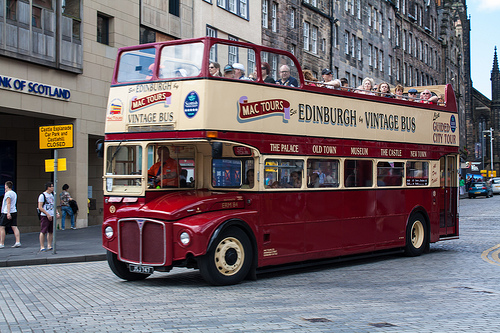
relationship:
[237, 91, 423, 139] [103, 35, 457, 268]
words on bus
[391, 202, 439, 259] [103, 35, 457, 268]
tires on bus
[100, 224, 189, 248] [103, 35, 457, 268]
lights on bus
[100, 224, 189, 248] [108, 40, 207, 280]
lights in front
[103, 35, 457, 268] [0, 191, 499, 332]
bus on street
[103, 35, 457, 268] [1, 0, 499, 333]
bus in city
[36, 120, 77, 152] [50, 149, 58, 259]
sign on pole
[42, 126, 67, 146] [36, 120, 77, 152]
letters on sign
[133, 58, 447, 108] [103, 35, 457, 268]
people on bus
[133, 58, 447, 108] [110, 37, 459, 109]
people on top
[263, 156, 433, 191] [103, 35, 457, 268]
windows on bus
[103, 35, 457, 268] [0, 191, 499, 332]
bus on road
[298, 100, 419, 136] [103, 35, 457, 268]
lettering on bus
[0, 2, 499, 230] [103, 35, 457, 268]
buildings behind bus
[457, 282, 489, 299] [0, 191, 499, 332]
drain on street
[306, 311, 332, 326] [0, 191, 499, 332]
spot on street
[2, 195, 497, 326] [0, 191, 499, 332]
tiles on road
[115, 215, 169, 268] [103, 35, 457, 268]
grate on bus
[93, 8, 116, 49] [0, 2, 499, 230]
window in building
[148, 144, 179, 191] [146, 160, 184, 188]
bus driver wearing shirt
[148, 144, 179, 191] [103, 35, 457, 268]
bus driver on bus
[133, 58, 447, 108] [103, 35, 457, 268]
passengers on bus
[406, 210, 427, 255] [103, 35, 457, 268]
tires on bus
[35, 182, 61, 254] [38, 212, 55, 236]
man wearing shorts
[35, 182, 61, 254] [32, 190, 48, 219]
man wearing backpack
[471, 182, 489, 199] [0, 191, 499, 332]
car on street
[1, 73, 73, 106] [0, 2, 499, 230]
sign on building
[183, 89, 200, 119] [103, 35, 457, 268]
decal on bus